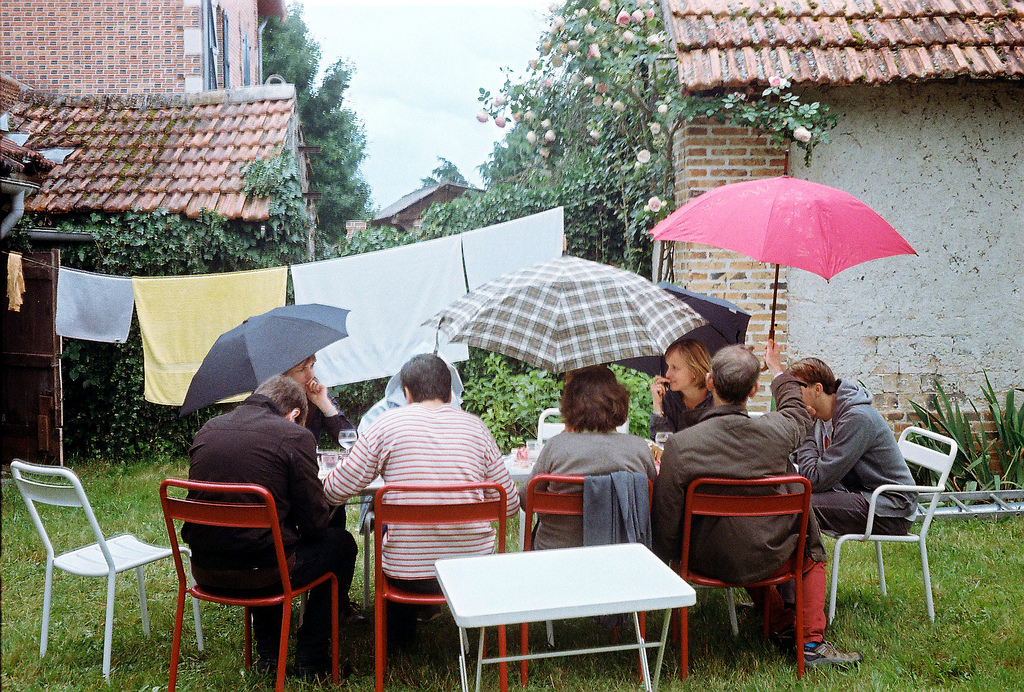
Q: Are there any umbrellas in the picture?
A: Yes, there is an umbrella.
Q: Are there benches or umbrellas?
A: Yes, there is an umbrella.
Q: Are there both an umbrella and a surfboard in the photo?
A: No, there is an umbrella but no surfboards.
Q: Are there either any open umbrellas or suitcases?
A: Yes, there is an open umbrella.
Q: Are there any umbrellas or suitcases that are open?
A: Yes, the umbrella is open.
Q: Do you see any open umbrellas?
A: Yes, there is an open umbrella.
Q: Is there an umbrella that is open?
A: Yes, there is an umbrella that is open.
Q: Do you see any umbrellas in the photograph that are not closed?
A: Yes, there is a open umbrella.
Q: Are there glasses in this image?
A: No, there are no glasses.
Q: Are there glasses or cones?
A: No, there are no glasses or cones.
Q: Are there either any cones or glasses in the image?
A: No, there are no glasses or cones.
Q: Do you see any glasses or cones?
A: No, there are no glasses or cones.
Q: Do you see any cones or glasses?
A: No, there are no glasses or cones.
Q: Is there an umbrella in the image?
A: Yes, there is an umbrella.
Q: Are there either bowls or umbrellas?
A: Yes, there is an umbrella.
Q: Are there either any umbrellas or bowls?
A: Yes, there is an umbrella.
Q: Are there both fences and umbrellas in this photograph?
A: No, there is an umbrella but no fences.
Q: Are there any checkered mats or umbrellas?
A: Yes, there is a checkered umbrella.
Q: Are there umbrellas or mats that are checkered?
A: Yes, the umbrella is checkered.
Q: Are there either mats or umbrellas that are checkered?
A: Yes, the umbrella is checkered.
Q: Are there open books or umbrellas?
A: Yes, there is an open umbrella.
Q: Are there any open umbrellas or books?
A: Yes, there is an open umbrella.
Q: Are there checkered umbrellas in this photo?
A: Yes, there is a checkered umbrella.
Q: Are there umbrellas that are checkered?
A: Yes, there is an umbrella that is checkered.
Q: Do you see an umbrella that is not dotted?
A: Yes, there is a checkered umbrella.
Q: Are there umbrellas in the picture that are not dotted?
A: Yes, there is a checkered umbrella.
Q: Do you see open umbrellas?
A: Yes, there is an open umbrella.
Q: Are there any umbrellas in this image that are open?
A: Yes, there is an umbrella that is open.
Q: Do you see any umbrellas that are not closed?
A: Yes, there is a open umbrella.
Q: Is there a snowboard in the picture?
A: No, there are no snowboards.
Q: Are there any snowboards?
A: No, there are no snowboards.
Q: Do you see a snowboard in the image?
A: No, there are no snowboards.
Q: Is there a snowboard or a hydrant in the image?
A: No, there are no snowboards or fire hydrants.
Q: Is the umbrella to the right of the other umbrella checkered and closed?
A: No, the umbrella is checkered but open.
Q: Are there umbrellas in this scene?
A: Yes, there is an umbrella.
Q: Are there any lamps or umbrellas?
A: Yes, there is an umbrella.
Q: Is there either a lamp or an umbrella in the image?
A: Yes, there is an umbrella.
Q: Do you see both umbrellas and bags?
A: No, there is an umbrella but no bags.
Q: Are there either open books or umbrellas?
A: Yes, there is an open umbrella.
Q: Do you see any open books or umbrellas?
A: Yes, there is an open umbrella.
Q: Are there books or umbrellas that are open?
A: Yes, the umbrella is open.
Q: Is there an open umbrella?
A: Yes, there is an open umbrella.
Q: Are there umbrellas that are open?
A: Yes, there is an umbrella that is open.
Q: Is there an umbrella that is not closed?
A: Yes, there is a open umbrella.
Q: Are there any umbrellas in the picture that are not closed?
A: Yes, there is a open umbrella.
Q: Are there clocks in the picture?
A: No, there are no clocks.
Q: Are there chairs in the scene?
A: Yes, there is a chair.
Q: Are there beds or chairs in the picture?
A: Yes, there is a chair.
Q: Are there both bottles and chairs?
A: No, there is a chair but no bottles.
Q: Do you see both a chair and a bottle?
A: No, there is a chair but no bottles.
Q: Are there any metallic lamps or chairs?
A: Yes, there is a metal chair.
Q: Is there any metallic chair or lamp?
A: Yes, there is a metal chair.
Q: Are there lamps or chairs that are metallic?
A: Yes, the chair is metallic.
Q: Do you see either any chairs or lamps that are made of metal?
A: Yes, the chair is made of metal.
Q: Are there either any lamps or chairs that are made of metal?
A: Yes, the chair is made of metal.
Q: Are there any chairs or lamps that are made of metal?
A: Yes, the chair is made of metal.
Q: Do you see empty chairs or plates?
A: Yes, there is an empty chair.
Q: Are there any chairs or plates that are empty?
A: Yes, the chair is empty.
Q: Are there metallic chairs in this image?
A: Yes, there is a metal chair.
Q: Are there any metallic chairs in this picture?
A: Yes, there is a metal chair.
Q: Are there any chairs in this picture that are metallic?
A: Yes, there is a chair that is metallic.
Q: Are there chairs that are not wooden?
A: Yes, there is a metallic chair.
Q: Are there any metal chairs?
A: Yes, there is a chair that is made of metal.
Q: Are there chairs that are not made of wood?
A: Yes, there is a chair that is made of metal.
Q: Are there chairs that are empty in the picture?
A: Yes, there is an empty chair.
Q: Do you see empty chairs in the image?
A: Yes, there is an empty chair.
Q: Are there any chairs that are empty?
A: Yes, there is a chair that is empty.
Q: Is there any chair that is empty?
A: Yes, there is a chair that is empty.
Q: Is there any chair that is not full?
A: Yes, there is a empty chair.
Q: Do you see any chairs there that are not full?
A: Yes, there is a empty chair.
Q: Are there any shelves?
A: No, there are no shelves.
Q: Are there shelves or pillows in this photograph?
A: No, there are no shelves or pillows.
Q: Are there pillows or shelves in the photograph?
A: No, there are no shelves or pillows.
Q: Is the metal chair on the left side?
A: Yes, the chair is on the left of the image.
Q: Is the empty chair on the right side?
A: No, the chair is on the left of the image.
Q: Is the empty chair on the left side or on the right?
A: The chair is on the left of the image.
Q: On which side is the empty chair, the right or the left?
A: The chair is on the left of the image.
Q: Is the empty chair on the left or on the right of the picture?
A: The chair is on the left of the image.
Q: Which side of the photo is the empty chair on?
A: The chair is on the left of the image.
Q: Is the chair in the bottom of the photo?
A: Yes, the chair is in the bottom of the image.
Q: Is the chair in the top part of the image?
A: No, the chair is in the bottom of the image.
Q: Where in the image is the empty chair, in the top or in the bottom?
A: The chair is in the bottom of the image.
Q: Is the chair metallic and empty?
A: Yes, the chair is metallic and empty.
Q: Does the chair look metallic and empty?
A: Yes, the chair is metallic and empty.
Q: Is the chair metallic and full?
A: No, the chair is metallic but empty.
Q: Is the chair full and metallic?
A: No, the chair is metallic but empty.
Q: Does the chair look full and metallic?
A: No, the chair is metallic but empty.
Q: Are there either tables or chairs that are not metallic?
A: No, there is a chair but it is metallic.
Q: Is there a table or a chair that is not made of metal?
A: No, there is a chair but it is made of metal.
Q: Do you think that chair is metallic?
A: Yes, the chair is metallic.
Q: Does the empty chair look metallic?
A: Yes, the chair is metallic.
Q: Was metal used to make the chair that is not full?
A: Yes, the chair is made of metal.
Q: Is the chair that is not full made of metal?
A: Yes, the chair is made of metal.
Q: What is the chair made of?
A: The chair is made of metal.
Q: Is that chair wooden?
A: No, the chair is metallic.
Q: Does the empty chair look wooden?
A: No, the chair is metallic.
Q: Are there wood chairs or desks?
A: No, there is a chair but it is metallic.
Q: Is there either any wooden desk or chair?
A: No, there is a chair but it is metallic.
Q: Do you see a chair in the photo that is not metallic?
A: No, there is a chair but it is metallic.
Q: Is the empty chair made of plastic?
A: No, the chair is made of metal.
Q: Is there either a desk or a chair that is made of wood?
A: No, there is a chair but it is made of metal.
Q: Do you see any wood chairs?
A: No, there is a chair but it is made of metal.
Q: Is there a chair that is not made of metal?
A: No, there is a chair but it is made of metal.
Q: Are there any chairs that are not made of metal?
A: No, there is a chair but it is made of metal.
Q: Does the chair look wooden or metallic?
A: The chair is metallic.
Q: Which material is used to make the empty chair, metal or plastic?
A: The chair is made of metal.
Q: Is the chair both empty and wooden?
A: No, the chair is empty but metallic.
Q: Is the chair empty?
A: Yes, the chair is empty.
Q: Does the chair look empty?
A: Yes, the chair is empty.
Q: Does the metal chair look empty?
A: Yes, the chair is empty.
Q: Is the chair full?
A: No, the chair is empty.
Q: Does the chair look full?
A: No, the chair is empty.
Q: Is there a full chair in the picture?
A: No, there is a chair but it is empty.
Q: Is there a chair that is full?
A: No, there is a chair but it is empty.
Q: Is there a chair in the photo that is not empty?
A: No, there is a chair but it is empty.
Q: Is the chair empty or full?
A: The chair is empty.